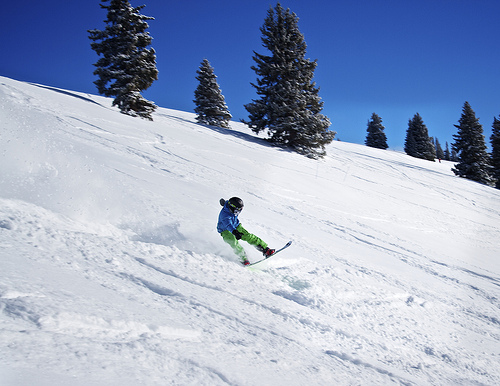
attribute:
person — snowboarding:
[214, 195, 278, 266]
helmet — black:
[228, 194, 246, 212]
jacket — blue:
[215, 206, 241, 232]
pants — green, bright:
[222, 222, 270, 262]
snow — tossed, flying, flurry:
[2, 92, 283, 269]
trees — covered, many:
[89, 3, 499, 186]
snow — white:
[2, 76, 500, 385]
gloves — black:
[231, 228, 245, 241]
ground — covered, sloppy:
[4, 78, 492, 379]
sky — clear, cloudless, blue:
[5, 1, 498, 159]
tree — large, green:
[241, 2, 339, 159]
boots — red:
[242, 247, 277, 268]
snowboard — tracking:
[240, 238, 295, 270]